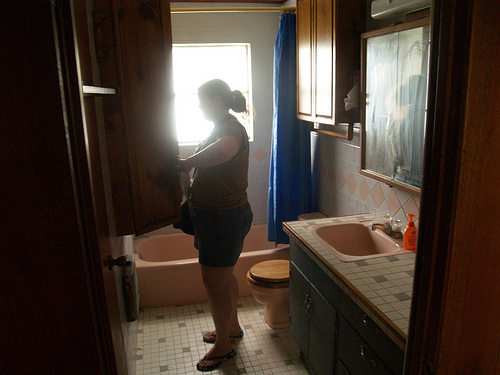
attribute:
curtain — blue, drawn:
[264, 8, 319, 231]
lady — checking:
[163, 61, 269, 372]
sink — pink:
[307, 216, 406, 277]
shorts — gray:
[186, 199, 254, 263]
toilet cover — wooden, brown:
[244, 253, 297, 288]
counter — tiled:
[355, 236, 423, 332]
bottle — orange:
[398, 207, 417, 253]